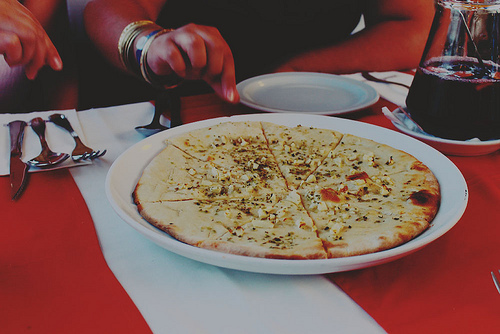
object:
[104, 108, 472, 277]
plate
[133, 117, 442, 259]
food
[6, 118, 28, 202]
utensil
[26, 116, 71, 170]
utensil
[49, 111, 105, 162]
utensil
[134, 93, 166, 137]
utensil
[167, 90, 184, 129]
utensil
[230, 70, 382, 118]
plate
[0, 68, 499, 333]
table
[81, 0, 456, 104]
person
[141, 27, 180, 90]
bracelets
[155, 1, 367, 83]
shirt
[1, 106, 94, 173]
napkin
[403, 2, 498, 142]
pitcher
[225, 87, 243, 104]
fingernail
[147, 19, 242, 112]
hand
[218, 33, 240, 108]
finger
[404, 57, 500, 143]
drink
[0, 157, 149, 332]
placemat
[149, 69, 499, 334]
placemat